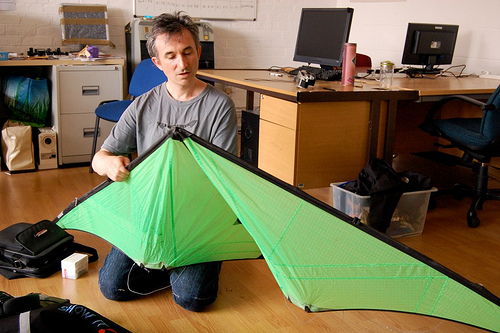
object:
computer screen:
[57, 2, 112, 47]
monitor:
[294, 9, 349, 62]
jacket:
[343, 161, 435, 235]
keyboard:
[288, 65, 342, 81]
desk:
[195, 67, 500, 191]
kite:
[48, 124, 500, 333]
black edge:
[51, 132, 499, 333]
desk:
[0, 55, 129, 168]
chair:
[86, 57, 168, 174]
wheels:
[476, 204, 484, 210]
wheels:
[453, 194, 465, 201]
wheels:
[427, 200, 437, 211]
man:
[90, 11, 240, 313]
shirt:
[99, 80, 239, 160]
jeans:
[96, 245, 224, 313]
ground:
[421, 197, 468, 263]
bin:
[329, 180, 439, 240]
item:
[347, 155, 410, 232]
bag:
[0, 219, 99, 280]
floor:
[2, 164, 498, 333]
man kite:
[46, 9, 500, 333]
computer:
[401, 22, 460, 74]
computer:
[289, 7, 355, 81]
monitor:
[63, 11, 105, 39]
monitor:
[401, 22, 460, 66]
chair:
[414, 82, 499, 229]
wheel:
[466, 215, 480, 228]